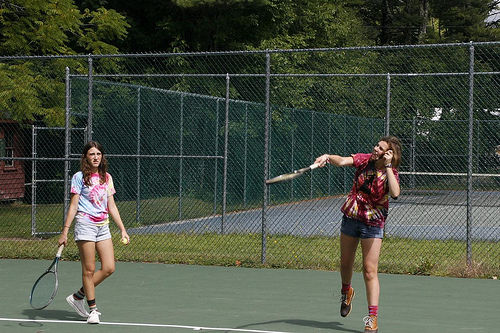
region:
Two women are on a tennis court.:
[26, 130, 403, 330]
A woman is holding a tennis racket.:
[27, 138, 108, 312]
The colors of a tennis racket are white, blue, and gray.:
[25, 238, 65, 313]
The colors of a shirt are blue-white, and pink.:
[65, 166, 117, 225]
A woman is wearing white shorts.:
[70, 213, 114, 246]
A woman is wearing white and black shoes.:
[63, 288, 103, 325]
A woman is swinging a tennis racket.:
[261, 143, 357, 190]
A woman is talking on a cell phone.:
[367, 135, 405, 200]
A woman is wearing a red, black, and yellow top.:
[338, 144, 402, 229]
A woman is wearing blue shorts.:
[334, 206, 389, 243]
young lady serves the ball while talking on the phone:
[260, 133, 407, 331]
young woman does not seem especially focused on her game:
[263, 130, 406, 331]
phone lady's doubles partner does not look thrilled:
[26, 134, 133, 330]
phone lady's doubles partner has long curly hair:
[76, 137, 111, 186]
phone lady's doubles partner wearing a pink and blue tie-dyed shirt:
[63, 165, 116, 225]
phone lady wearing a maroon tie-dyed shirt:
[335, 146, 401, 228]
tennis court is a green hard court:
[1, 259, 499, 331]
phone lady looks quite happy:
[366, 132, 403, 168]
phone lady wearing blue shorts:
[335, 210, 389, 242]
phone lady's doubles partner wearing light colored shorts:
[72, 211, 114, 245]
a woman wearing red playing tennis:
[257, 137, 401, 332]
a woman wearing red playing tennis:
[27, 138, 131, 327]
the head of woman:
[78, 137, 109, 173]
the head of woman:
[370, 132, 399, 166]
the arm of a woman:
[105, 188, 130, 246]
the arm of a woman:
[320, 150, 370, 170]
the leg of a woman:
[360, 232, 385, 312]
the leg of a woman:
[75, 235, 95, 301]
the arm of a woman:
[55, 185, 76, 250]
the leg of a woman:
[334, 233, 359, 305]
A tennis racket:
[263, 162, 319, 183]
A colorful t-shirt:
[71, 169, 116, 224]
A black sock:
[76, 284, 86, 298]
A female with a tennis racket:
[30, 139, 128, 321]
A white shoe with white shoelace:
[86, 309, 101, 321]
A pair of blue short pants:
[342, 214, 383, 236]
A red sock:
[366, 302, 378, 314]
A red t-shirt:
[343, 151, 398, 224]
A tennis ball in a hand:
[120, 235, 126, 242]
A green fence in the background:
[65, 68, 497, 268]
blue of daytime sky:
[484, 4, 498, 26]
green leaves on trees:
[0, 7, 479, 192]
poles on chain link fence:
[2, 41, 497, 265]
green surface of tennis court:
[2, 257, 498, 331]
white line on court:
[1, 316, 246, 331]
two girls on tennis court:
[30, 136, 401, 328]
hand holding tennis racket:
[30, 234, 67, 309]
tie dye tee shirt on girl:
[72, 171, 116, 222]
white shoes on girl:
[66, 295, 101, 324]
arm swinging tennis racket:
[264, 151, 366, 188]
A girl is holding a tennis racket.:
[28, 237, 75, 309]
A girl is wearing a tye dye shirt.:
[60, 167, 115, 222]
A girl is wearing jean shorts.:
[76, 215, 113, 247]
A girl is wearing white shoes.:
[57, 290, 103, 327]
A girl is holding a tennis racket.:
[255, 148, 326, 188]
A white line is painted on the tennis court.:
[121, 313, 189, 332]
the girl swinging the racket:
[266, 131, 401, 331]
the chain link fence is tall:
[0, 38, 499, 278]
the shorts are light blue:
[73, 219, 109, 242]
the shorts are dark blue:
[341, 214, 384, 239]